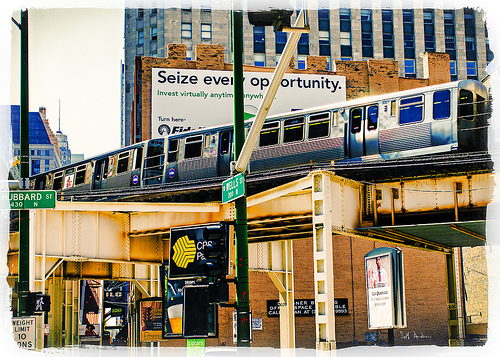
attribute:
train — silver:
[81, 80, 499, 194]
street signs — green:
[8, 191, 61, 215]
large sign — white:
[153, 70, 347, 141]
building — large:
[134, 51, 447, 132]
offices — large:
[128, 11, 477, 57]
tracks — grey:
[132, 155, 487, 210]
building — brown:
[50, 100, 75, 160]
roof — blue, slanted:
[10, 105, 55, 147]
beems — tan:
[367, 180, 489, 207]